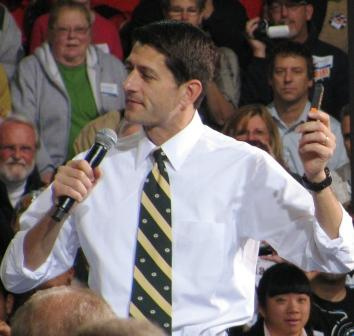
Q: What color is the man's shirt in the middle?
A: White.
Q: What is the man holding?
A: Microphone.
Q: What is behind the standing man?
A: An audience.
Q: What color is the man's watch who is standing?
A: Black.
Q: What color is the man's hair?
A: Brown.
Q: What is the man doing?
A: Giving a speech.